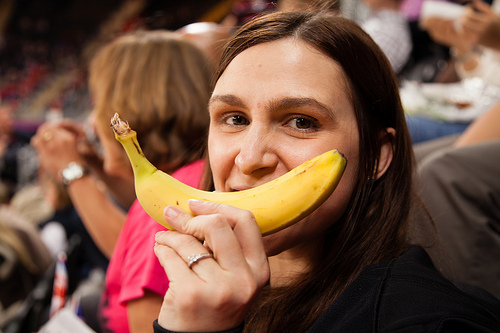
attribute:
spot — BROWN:
[171, 200, 192, 212]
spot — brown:
[172, 194, 184, 206]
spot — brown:
[303, 175, 324, 196]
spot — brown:
[290, 164, 311, 178]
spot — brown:
[127, 132, 147, 160]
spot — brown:
[111, 135, 129, 142]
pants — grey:
[406, 120, 482, 287]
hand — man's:
[22, 110, 91, 179]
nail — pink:
[153, 197, 209, 250]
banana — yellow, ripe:
[109, 109, 352, 241]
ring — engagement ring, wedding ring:
[184, 248, 214, 268]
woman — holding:
[158, 12, 498, 331]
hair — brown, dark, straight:
[214, 3, 418, 327]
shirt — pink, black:
[102, 153, 205, 331]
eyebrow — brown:
[202, 91, 355, 120]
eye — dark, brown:
[211, 109, 250, 132]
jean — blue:
[407, 106, 468, 139]